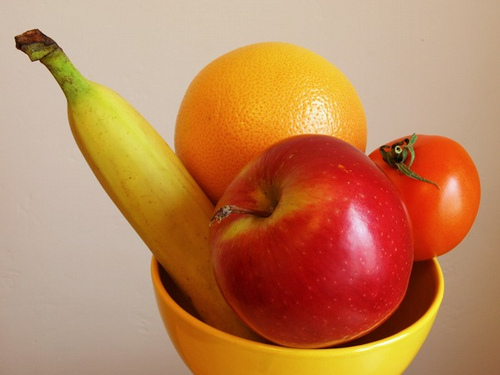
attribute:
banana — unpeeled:
[33, 37, 213, 289]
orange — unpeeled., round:
[168, 37, 368, 211]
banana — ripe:
[13, 16, 223, 300]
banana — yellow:
[12, 30, 258, 340]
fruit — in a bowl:
[170, 57, 380, 174]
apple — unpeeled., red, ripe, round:
[196, 120, 425, 355]